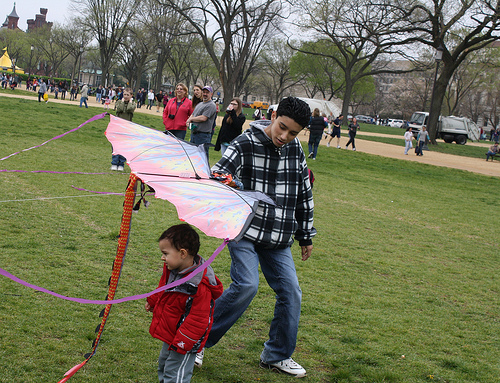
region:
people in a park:
[6, 56, 443, 380]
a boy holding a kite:
[63, 98, 332, 380]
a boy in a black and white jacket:
[221, 101, 322, 248]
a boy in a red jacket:
[145, 231, 225, 356]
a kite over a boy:
[85, 91, 268, 380]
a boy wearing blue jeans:
[209, 235, 305, 356]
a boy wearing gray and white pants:
[161, 339, 196, 380]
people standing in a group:
[161, 79, 246, 143]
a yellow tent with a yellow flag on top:
[0, 43, 19, 70]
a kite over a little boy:
[91, 103, 272, 380]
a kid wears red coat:
[138, 217, 228, 379]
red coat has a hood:
[138, 264, 228, 356]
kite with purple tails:
[1, 103, 266, 310]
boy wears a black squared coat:
[196, 85, 326, 380]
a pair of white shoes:
[190, 348, 310, 380]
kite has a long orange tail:
[53, 113, 140, 380]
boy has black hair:
[216, 78, 333, 203]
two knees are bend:
[220, 265, 315, 311]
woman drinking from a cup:
[215, 90, 253, 152]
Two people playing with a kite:
[101, 95, 313, 380]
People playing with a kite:
[103, 95, 314, 380]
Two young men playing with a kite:
[103, 95, 319, 381]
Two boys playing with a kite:
[102, 98, 319, 381]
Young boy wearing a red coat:
[145, 224, 222, 380]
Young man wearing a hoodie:
[223, 93, 316, 377]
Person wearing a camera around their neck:
[160, 82, 188, 132]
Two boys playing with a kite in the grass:
[101, 95, 317, 381]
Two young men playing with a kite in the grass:
[100, 94, 317, 381]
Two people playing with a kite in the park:
[104, 96, 326, 381]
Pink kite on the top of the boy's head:
[102, 107, 278, 251]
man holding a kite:
[104, 63, 311, 381]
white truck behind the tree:
[404, 106, 477, 142]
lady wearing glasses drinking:
[216, 87, 243, 154]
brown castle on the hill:
[6, 5, 56, 36]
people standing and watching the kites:
[165, 69, 220, 144]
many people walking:
[306, 103, 464, 160]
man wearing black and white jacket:
[225, 85, 325, 260]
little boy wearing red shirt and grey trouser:
[147, 225, 212, 379]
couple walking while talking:
[403, 118, 430, 159]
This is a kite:
[11, 103, 256, 297]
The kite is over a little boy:
[4, 110, 250, 373]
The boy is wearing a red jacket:
[138, 226, 221, 380]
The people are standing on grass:
[11, 269, 348, 381]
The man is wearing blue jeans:
[208, 235, 318, 373]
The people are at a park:
[5, 20, 498, 366]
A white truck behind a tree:
[402, 97, 478, 145]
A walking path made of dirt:
[317, 111, 499, 181]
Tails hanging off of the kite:
[6, 132, 135, 309]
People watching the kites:
[104, 58, 244, 126]